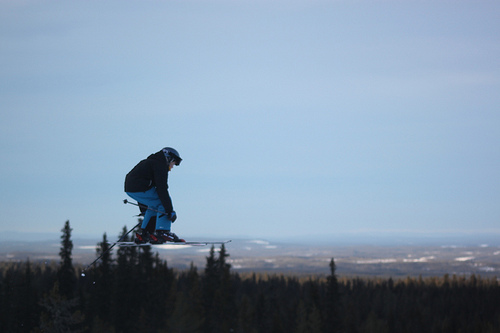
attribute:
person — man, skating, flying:
[120, 141, 201, 238]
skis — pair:
[105, 237, 234, 251]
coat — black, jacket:
[122, 151, 177, 208]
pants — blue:
[122, 184, 181, 237]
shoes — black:
[135, 227, 174, 235]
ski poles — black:
[86, 195, 185, 272]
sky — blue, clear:
[4, 2, 497, 243]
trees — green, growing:
[56, 226, 337, 323]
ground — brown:
[247, 246, 499, 277]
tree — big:
[45, 220, 92, 328]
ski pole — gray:
[123, 198, 169, 218]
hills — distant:
[1, 239, 498, 276]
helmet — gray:
[165, 148, 181, 155]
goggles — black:
[168, 158, 185, 164]